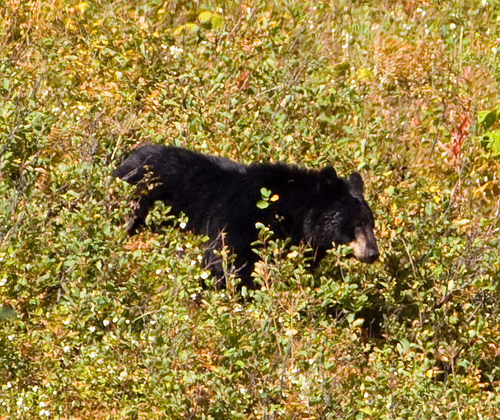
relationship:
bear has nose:
[112, 136, 377, 290] [364, 248, 378, 261]